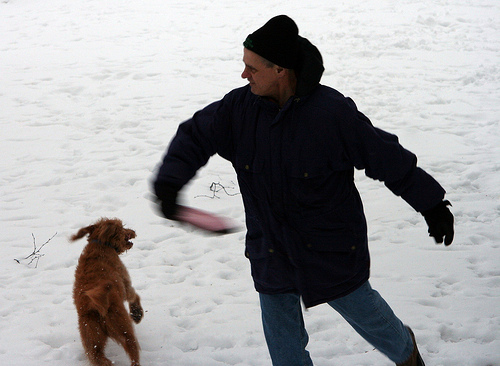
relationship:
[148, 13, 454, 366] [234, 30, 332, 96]
man has head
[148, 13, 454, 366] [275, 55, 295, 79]
man has ear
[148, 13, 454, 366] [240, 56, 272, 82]
man has eye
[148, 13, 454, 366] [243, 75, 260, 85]
man has mouth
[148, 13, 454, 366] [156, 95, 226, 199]
man has arm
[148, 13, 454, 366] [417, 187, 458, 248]
man has hand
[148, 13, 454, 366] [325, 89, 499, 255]
man has arm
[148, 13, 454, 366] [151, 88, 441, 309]
man has coat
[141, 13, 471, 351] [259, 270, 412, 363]
man has jeans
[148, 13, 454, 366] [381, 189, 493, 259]
man has gloves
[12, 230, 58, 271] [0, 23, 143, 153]
stick in snow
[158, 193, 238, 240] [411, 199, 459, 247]
frisbee in hand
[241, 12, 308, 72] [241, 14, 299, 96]
hat on head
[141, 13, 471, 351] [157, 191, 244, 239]
man throwing frisbee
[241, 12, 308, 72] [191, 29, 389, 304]
hat on man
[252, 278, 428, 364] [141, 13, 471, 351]
jeans on man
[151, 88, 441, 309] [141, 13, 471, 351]
coat on man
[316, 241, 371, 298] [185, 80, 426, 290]
pocket on coat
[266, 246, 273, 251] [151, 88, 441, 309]
button on coat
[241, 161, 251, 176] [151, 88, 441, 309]
button on coat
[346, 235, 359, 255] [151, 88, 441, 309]
button on coat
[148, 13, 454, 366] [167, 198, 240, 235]
man holding frisbee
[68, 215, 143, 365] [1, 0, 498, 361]
dog in snow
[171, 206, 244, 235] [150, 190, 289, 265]
frisbee in hand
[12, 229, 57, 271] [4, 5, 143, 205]
stick in snow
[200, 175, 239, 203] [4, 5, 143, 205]
stick in snow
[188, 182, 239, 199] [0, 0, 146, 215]
stick in snow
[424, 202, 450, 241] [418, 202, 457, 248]
glove on hand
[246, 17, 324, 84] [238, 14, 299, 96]
hat on head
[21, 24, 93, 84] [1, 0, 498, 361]
footprints in snow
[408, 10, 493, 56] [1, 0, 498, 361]
footprints in snow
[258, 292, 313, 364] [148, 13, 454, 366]
leg of man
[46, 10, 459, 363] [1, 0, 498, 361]
they are playing in snow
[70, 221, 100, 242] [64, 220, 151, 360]
ear of dog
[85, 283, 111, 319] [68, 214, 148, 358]
tail of dog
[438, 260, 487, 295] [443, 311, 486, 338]
footprints in snow